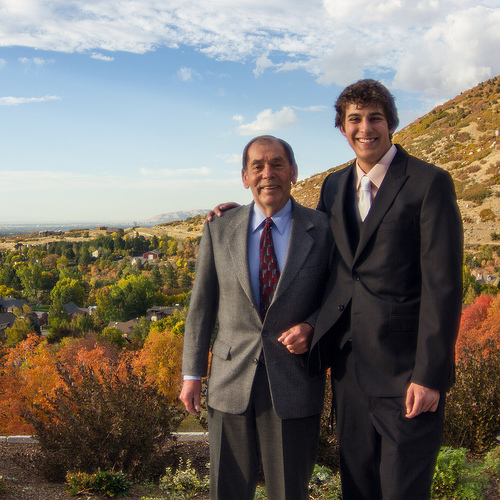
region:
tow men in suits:
[170, 73, 469, 497]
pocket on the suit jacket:
[207, 332, 237, 374]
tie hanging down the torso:
[251, 220, 291, 325]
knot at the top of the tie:
[260, 215, 273, 235]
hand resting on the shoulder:
[199, 198, 235, 225]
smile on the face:
[353, 136, 377, 144]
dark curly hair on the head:
[323, 75, 401, 138]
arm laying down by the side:
[397, 168, 464, 425]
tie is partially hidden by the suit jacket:
[338, 177, 383, 270]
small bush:
[14, 348, 185, 486]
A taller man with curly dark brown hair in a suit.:
[204, 77, 464, 499]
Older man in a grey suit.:
[178, 134, 332, 499]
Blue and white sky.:
[0, 2, 499, 226]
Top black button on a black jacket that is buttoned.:
[351, 272, 361, 282]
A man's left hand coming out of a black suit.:
[404, 381, 441, 418]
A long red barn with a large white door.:
[141, 248, 163, 260]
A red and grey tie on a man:
[258, 217, 281, 323]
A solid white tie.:
[358, 175, 371, 222]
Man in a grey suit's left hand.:
[274, 324, 314, 360]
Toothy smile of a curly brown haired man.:
[356, 136, 379, 145]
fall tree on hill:
[28, 375, 71, 414]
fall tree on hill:
[113, 426, 154, 470]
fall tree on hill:
[147, 345, 174, 373]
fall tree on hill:
[467, 308, 498, 360]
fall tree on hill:
[92, 287, 132, 321]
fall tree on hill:
[97, 286, 119, 313]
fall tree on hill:
[460, 150, 474, 163]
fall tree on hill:
[132, 347, 158, 379]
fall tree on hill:
[10, 351, 45, 401]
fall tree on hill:
[76, 345, 108, 379]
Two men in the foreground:
[170, 62, 465, 497]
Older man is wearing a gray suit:
[170, 120, 335, 490]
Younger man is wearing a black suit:
[300, 73, 475, 496]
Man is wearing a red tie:
[248, 210, 285, 320]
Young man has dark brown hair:
[316, 76, 413, 161]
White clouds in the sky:
[3, 2, 499, 231]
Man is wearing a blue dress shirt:
[238, 203, 301, 323]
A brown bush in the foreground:
[16, 347, 191, 499]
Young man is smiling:
[318, 69, 421, 181]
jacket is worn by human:
[318, 146, 463, 438]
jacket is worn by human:
[180, 198, 328, 415]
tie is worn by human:
[257, 218, 278, 316]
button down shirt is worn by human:
[350, 142, 399, 235]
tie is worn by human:
[356, 175, 373, 223]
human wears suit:
[315, 80, 465, 499]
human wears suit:
[176, 134, 329, 499]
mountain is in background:
[149, 77, 497, 248]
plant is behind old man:
[21, 351, 180, 479]